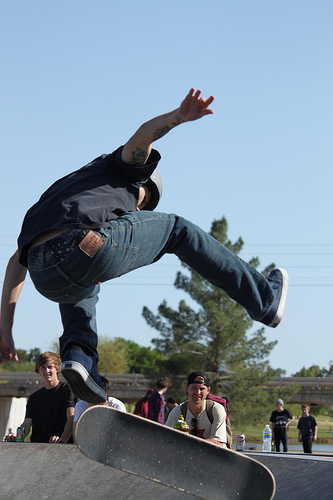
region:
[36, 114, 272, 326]
this is a man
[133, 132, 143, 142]
the man is light skinned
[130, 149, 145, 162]
this is a tattoo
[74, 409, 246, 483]
this is a skate board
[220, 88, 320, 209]
this is the sky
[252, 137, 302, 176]
the sky is blue in color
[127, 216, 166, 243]
this is a trouser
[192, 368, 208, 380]
this is a cap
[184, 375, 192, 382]
the cap is black in color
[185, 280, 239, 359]
this is a tree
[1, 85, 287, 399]
guy above skateboard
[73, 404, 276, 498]
black skateboard under guy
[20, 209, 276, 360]
blue jeans on guy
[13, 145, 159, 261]
navy blue tshirt on guy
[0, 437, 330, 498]
black ramp under skateboard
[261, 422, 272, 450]
clear plastic water bottle on ramp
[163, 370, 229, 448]
man leaning on ramp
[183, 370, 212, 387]
black baseball cap on man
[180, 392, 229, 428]
backpack on man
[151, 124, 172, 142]
tattoo on guy skateboarding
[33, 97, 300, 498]
a young man performing a skateboard trick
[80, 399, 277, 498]
the top of a black skateboard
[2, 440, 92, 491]
a concrete slope in a skate park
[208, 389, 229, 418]
a red backpack on a man's back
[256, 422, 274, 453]
a bottle of water on the edge of the ramp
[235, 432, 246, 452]
a silver can of soda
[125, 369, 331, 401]
an old train on a track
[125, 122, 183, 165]
tattoos on the underside of a man's right arm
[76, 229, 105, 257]
the brown and red label on the skateboarder's jeans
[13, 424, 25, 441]
a green mountain dew can on the ramp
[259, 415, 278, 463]
plastic bottle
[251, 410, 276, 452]
plastic bottle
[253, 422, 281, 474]
plastic bottle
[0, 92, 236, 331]
this is a boy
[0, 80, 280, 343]
the boy is skating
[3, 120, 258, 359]
the boy is on air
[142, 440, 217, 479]
this is a skate board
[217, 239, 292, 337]
the leg is in front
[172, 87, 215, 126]
the hand is apart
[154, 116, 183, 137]
the hand is tattoed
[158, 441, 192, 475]
the board is black in color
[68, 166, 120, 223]
the t shirt is black in color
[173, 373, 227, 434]
the man is watching